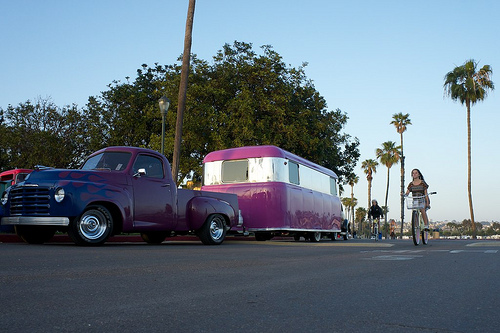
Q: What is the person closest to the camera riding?
A: A bicycle.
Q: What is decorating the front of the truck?
A: Blue flames decal.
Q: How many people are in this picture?
A: Two.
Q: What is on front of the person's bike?
A: A basket.